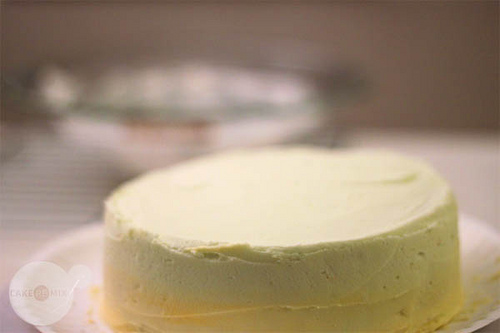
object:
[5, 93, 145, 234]
grate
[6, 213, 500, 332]
dish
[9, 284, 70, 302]
number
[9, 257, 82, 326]
logo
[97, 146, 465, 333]
cake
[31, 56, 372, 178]
bowl